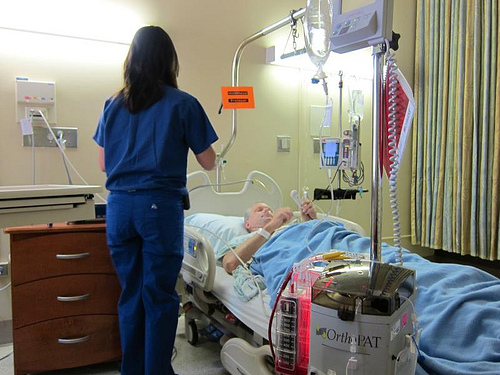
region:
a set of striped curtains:
[407, 0, 495, 263]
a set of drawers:
[5, 215, 135, 367]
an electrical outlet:
[25, 127, 80, 152]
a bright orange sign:
[220, 83, 260, 109]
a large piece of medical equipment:
[266, 243, 422, 373]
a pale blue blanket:
[256, 215, 496, 372]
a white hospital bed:
[172, 165, 442, 373]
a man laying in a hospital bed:
[181, 165, 483, 356]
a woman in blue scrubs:
[91, 20, 223, 370]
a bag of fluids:
[300, 0, 335, 70]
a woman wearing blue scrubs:
[95, 22, 220, 357]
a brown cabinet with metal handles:
[10, 223, 102, 360]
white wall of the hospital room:
[16, 8, 101, 60]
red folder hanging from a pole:
[355, 60, 411, 189]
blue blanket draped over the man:
[235, 213, 485, 346]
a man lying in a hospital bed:
[211, 195, 364, 250]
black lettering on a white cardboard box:
[320, 327, 381, 352]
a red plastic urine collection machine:
[266, 268, 321, 373]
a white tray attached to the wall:
[0, 173, 114, 214]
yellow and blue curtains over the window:
[411, 5, 490, 249]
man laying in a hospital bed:
[222, 200, 497, 361]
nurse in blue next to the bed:
[93, 23, 217, 371]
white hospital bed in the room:
[154, 162, 499, 374]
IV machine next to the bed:
[220, 0, 419, 373]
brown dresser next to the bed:
[2, 215, 147, 372]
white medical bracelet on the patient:
[256, 226, 273, 238]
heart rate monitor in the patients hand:
[289, 184, 314, 219]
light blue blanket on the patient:
[251, 232, 498, 370]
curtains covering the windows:
[407, 0, 499, 264]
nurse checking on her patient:
[96, 23, 221, 372]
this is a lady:
[68, 17, 208, 290]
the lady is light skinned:
[201, 152, 218, 168]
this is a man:
[244, 192, 336, 274]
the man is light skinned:
[244, 238, 253, 251]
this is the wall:
[53, 15, 93, 62]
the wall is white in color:
[190, 9, 225, 46]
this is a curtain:
[419, 12, 489, 168]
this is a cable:
[376, 49, 442, 281]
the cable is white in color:
[381, 98, 404, 230]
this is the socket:
[14, 106, 54, 135]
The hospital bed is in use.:
[171, 138, 489, 373]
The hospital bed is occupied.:
[176, 149, 498, 374]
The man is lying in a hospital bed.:
[178, 165, 498, 372]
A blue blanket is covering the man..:
[178, 156, 498, 373]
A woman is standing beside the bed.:
[91, 6, 492, 373]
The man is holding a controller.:
[183, 137, 498, 374]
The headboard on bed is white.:
[173, 158, 499, 373]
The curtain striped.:
[379, 0, 498, 374]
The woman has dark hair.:
[81, 19, 227, 374]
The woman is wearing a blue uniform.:
[86, 20, 225, 373]